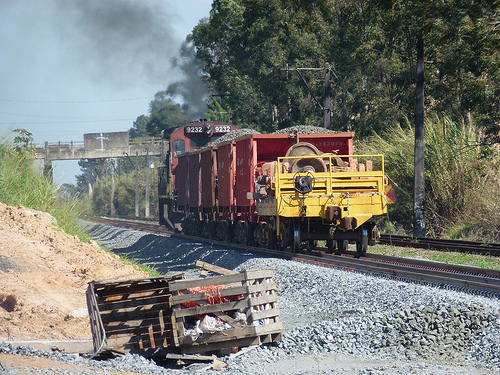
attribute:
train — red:
[156, 110, 393, 254]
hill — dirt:
[6, 210, 48, 301]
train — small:
[146, 110, 407, 266]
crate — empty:
[84, 272, 184, 358]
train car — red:
[233, 133, 353, 244]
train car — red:
[215, 137, 235, 241]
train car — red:
[199, 143, 219, 242]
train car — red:
[185, 148, 203, 238]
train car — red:
[171, 149, 190, 236]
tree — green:
[375, 0, 483, 235]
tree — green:
[310, 4, 394, 134]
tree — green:
[222, 0, 346, 127]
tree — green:
[187, 0, 243, 75]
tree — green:
[147, 95, 191, 135]